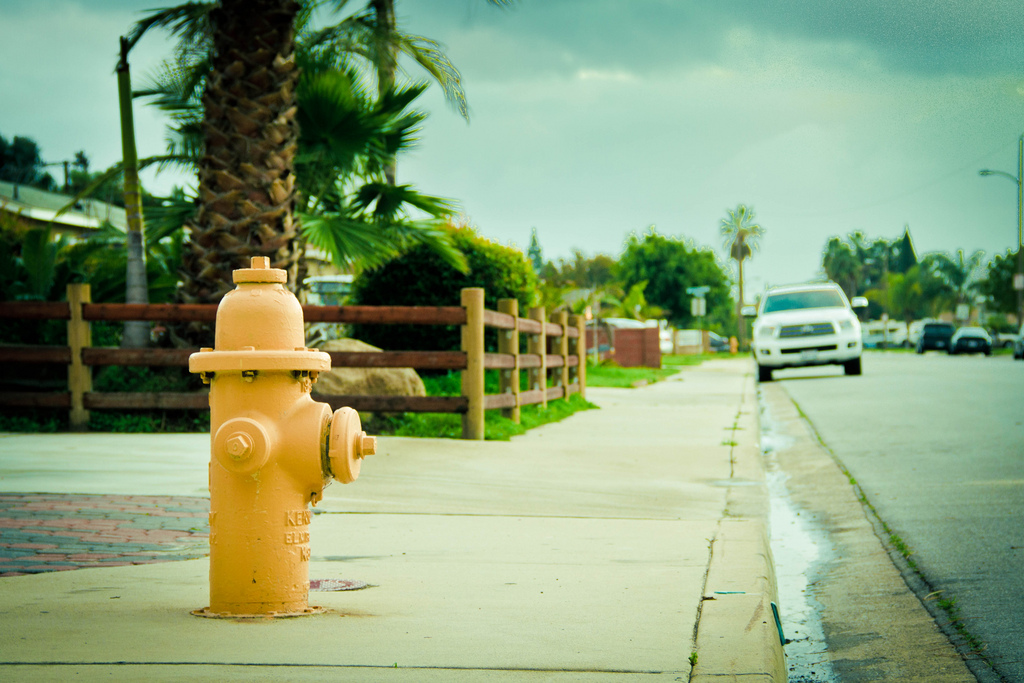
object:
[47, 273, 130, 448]
fence post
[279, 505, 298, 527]
letters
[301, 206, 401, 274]
leaves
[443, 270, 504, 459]
fence post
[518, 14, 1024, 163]
clouds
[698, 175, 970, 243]
dark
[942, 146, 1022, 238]
light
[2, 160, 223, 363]
home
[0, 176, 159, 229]
roof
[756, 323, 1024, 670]
street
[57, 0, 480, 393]
tree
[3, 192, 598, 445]
yard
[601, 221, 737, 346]
tree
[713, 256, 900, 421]
truck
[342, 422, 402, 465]
bolt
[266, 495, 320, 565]
writing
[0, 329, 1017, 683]
ground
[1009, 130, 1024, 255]
pole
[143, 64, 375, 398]
trunk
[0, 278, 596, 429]
fence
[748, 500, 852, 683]
water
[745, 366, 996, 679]
gutter